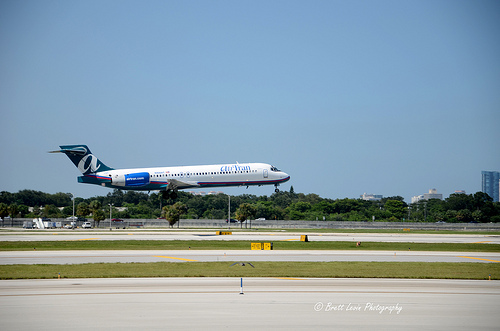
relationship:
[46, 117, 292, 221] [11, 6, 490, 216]
airplane taking off into the air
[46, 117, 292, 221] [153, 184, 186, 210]
airplane has landing gear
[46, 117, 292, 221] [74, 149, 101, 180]
airplane has white letter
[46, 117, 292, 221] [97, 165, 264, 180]
airplane has windows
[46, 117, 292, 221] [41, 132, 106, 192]
airplane has tail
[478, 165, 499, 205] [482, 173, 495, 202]
skyscraper has windows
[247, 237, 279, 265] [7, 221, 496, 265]
squares are on runway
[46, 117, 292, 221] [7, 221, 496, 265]
airplane above runway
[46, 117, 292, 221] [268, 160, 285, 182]
airplane has pilot window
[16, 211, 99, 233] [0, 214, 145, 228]
cars in parking lot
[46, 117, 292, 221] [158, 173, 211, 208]
airplane has wing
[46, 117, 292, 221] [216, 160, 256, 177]
airplane has writing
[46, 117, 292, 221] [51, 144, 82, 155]
airplane has tail fin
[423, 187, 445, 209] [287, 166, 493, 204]
building in background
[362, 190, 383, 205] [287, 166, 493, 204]
building in background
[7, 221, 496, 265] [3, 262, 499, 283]
runway has grass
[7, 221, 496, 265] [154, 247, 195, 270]
runway has yellow stripe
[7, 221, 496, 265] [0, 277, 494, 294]
runway has curb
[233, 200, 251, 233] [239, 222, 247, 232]
tree has trunk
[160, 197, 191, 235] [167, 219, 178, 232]
tree has trunk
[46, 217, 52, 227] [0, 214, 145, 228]
car in parking lot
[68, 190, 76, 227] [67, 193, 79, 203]
pole has lights